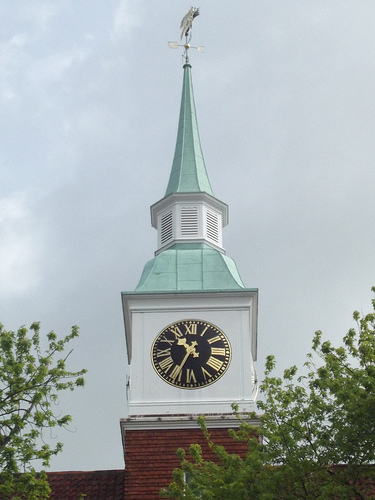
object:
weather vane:
[166, 0, 206, 64]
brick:
[121, 428, 261, 499]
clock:
[149, 317, 234, 391]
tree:
[183, 302, 373, 499]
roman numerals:
[183, 319, 196, 337]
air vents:
[157, 201, 224, 246]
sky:
[1, 0, 117, 177]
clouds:
[11, 23, 28, 48]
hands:
[169, 337, 198, 381]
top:
[118, 1, 260, 295]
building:
[3, 468, 122, 499]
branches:
[304, 440, 331, 465]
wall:
[120, 302, 258, 418]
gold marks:
[199, 322, 213, 337]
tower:
[120, 9, 263, 499]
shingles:
[131, 243, 247, 292]